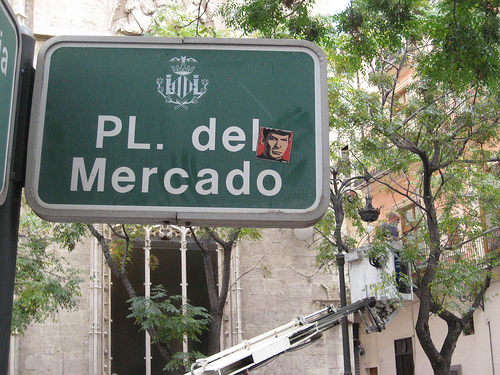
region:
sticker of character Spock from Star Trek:
[259, 125, 296, 162]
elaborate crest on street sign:
[154, 53, 211, 107]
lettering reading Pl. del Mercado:
[60, 113, 284, 198]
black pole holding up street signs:
[0, 31, 33, 373]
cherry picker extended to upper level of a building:
[182, 244, 419, 374]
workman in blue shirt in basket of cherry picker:
[377, 210, 405, 242]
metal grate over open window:
[92, 229, 247, 373]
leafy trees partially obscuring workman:
[158, 0, 494, 372]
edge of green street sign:
[0, 4, 17, 210]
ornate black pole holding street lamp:
[323, 167, 381, 374]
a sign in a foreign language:
[22, 0, 344, 275]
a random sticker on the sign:
[240, 105, 318, 193]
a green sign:
[53, 2, 321, 247]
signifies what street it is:
[29, 6, 415, 319]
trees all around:
[286, 17, 466, 353]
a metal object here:
[73, 267, 430, 360]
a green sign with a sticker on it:
[40, 31, 454, 313]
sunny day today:
[175, 8, 470, 350]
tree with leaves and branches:
[371, 139, 486, 367]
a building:
[37, 153, 379, 338]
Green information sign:
[34, 32, 334, 228]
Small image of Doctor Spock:
[255, 124, 295, 166]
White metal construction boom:
[179, 241, 413, 372]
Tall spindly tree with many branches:
[326, 29, 498, 374]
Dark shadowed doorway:
[103, 237, 240, 374]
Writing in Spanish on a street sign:
[71, 112, 286, 198]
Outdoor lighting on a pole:
[327, 162, 382, 372]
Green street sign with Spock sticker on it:
[33, 35, 331, 230]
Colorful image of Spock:
[253, 125, 295, 163]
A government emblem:
[151, 53, 215, 114]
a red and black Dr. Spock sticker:
[258, 123, 301, 165]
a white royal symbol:
[154, 52, 216, 109]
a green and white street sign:
[17, 32, 319, 219]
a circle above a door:
[393, 334, 411, 354]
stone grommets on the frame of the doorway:
[106, 290, 116, 363]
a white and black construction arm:
[232, 314, 383, 359]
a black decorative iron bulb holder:
[357, 202, 382, 221]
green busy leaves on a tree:
[136, 292, 202, 342]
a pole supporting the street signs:
[0, 211, 26, 328]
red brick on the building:
[377, 192, 404, 207]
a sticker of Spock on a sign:
[252, 122, 297, 165]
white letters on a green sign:
[83, 123, 161, 189]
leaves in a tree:
[353, 22, 396, 78]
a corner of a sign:
[16, 163, 63, 233]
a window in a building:
[388, 331, 417, 373]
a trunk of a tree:
[410, 311, 443, 370]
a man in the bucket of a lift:
[368, 201, 411, 268]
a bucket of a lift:
[335, 244, 426, 319]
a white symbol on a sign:
[144, 54, 229, 108]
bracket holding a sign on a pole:
[25, 21, 65, 52]